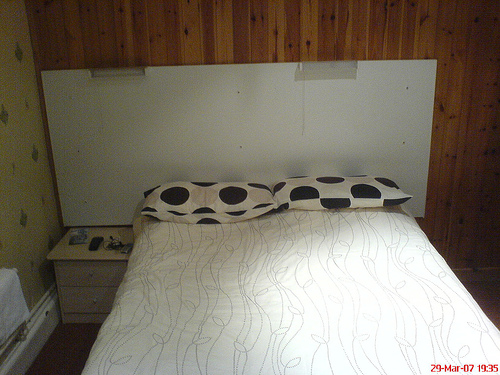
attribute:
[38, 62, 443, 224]
board — white, handled, large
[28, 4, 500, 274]
wall — wooden, knotted, designed, old, shaded, brown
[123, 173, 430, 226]
pillows — black, designed, edged, circled, white, dotted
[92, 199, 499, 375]
bed — lined, large, gray, part, small, squiggly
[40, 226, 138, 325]
stand — smooth, brown, small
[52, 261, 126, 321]
drawers — small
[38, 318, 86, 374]
floor — brown, white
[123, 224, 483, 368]
sheet — lined, curly